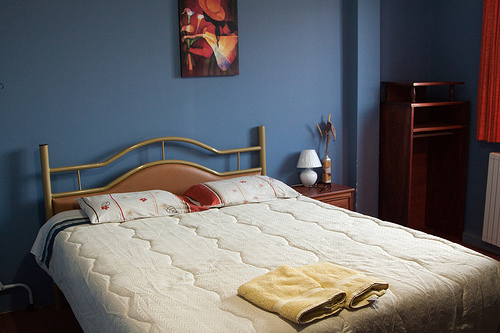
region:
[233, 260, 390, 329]
Two yellow towels on bed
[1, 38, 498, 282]
Bedroom has blue walls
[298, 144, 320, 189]
White lamp on side table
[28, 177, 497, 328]
White bedspread on bed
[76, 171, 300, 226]
Two pillows on bed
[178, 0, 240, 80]
Colorful picture hanging on blue wall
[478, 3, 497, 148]
Red curtain hanging from wall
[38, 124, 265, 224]
Brown metal headboard between bed and wall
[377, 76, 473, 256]
Cherry wood podium in room corner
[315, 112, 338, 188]
Vase with flower on side table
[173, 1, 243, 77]
orange black yellow and green painting of a lady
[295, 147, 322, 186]
small white lamp with white lampshade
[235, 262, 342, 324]
folded yellow fluffy towel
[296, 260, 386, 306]
yellow folded fluffy towel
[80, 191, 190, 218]
white red and black pillow case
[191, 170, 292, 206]
white red and black pillow case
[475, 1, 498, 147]
long bright red curtain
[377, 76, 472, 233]
tall wooden piece of furniture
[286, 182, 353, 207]
small wooden night table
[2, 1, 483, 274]
soft blue wall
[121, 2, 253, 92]
a picture hanging on a wall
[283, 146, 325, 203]
a small white lamp on a table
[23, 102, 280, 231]
a metal head board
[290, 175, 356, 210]
a small wooden table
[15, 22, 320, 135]
a blue wall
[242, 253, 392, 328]
two bath towels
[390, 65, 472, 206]
a wooden book case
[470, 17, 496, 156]
a red curtain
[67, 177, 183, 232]
a floral printed pillow case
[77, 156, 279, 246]
two pillows on a bed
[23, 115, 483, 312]
blue bedroom with white bed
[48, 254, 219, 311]
white cover on double bed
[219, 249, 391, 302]
two yellow towels on top of bed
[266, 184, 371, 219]
small nightstand next to bed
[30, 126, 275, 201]
light tan colored headboard for bed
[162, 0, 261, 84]
colorful artwork above bed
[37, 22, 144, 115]
walls are deep blue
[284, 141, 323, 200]
small white light on nightstand with shade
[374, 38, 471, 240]
wooden shelves are empty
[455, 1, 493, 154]
orange draperies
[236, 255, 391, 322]
creme colored towel sit on bed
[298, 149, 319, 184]
a small white lamp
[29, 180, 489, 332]
a large white bed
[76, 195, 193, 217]
a pillow on the bed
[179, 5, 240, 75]
a picture on the wall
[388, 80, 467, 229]
a wooden book case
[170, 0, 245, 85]
A painting on the wall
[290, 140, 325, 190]
A small white lamp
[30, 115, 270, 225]
The headboard of a bed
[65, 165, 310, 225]
Two pillows on a bed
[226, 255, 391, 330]
A folded yellow towel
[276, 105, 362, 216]
Lamp and flower on a table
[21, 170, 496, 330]
White bedspread on the bed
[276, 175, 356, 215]
A brown wooden end table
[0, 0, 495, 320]
The walls have been painted blue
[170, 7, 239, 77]
a picture on the wall